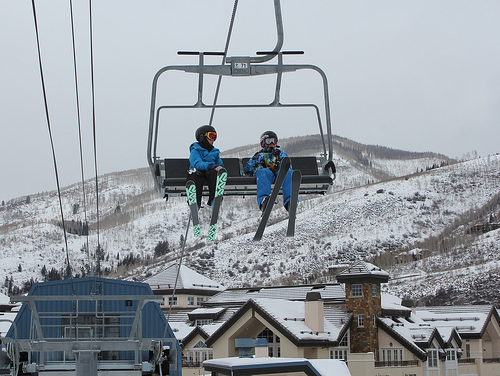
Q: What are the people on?
A: A ski lift.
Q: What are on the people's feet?
A: Skis.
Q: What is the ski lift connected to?
A: Wires.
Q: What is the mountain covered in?
A: Snow.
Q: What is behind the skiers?
A: Mountains.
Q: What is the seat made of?
A: Metal.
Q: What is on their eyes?
A: Glasses.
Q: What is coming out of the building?
A: Cables.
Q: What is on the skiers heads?
A: Helmets.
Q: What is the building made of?
A: Metal.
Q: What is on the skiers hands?
A: Gloves.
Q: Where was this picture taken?
A: On a ski lift.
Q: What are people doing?
A: Sitting on a ski lift.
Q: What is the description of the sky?
A: A pale blue.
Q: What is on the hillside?
A: Snow and trees.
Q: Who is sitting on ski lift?
A: Two skiers.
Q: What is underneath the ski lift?
A: Houses.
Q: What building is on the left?
A: A ski lodge.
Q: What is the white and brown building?
A: A house.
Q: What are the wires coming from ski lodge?
A: The are lift lines.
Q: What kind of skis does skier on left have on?
A: Blue green print.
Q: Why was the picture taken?
A: To capture the people.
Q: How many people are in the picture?
A: Two.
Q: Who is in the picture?
A: A man and women.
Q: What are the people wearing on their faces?
A: Goggles.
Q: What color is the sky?
A: Gray.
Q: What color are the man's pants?
A: Blue.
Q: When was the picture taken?
A: During the day.